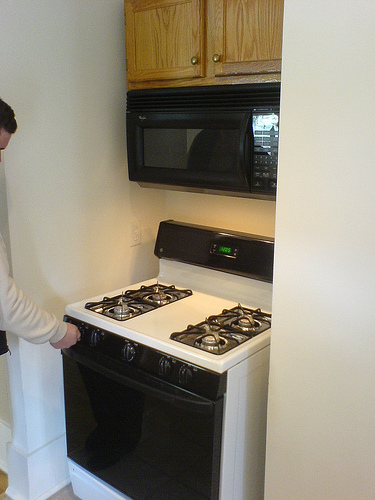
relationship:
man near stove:
[0, 99, 70, 499] [50, 223, 285, 499]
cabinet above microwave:
[125, 0, 284, 84] [116, 86, 282, 196]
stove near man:
[50, 223, 285, 499] [0, 99, 70, 499]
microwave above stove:
[116, 86, 282, 196] [50, 223, 285, 499]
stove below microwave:
[50, 223, 285, 499] [116, 86, 282, 196]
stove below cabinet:
[50, 223, 285, 499] [125, 0, 284, 84]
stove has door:
[61, 219, 275, 499] [61, 344, 223, 498]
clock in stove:
[216, 246, 229, 253] [50, 223, 285, 499]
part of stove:
[154, 218, 278, 284] [50, 223, 285, 499]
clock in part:
[216, 246, 229, 253] [154, 218, 278, 284]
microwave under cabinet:
[125, 91, 283, 196] [126, 2, 284, 84]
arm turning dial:
[0, 241, 70, 345] [72, 324, 84, 344]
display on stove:
[214, 242, 233, 256] [50, 223, 285, 499]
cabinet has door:
[126, 2, 284, 84] [126, 2, 206, 79]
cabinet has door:
[126, 2, 284, 84] [213, 3, 281, 75]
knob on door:
[190, 56, 197, 66] [122, 1, 207, 83]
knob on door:
[212, 54, 224, 64] [213, 3, 281, 75]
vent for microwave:
[125, 85, 282, 109] [116, 86, 282, 196]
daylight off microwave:
[250, 114, 279, 157] [116, 86, 282, 196]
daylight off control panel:
[250, 114, 279, 157] [252, 113, 277, 197]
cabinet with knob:
[126, 2, 284, 84] [190, 57, 202, 66]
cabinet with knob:
[126, 2, 284, 84] [210, 55, 222, 63]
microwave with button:
[116, 86, 282, 196] [252, 128, 262, 136]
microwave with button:
[116, 86, 282, 196] [261, 130, 269, 135]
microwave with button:
[116, 86, 282, 196] [268, 129, 277, 137]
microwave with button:
[116, 86, 282, 196] [252, 145, 265, 153]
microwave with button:
[116, 86, 282, 196] [262, 148, 270, 153]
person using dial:
[0, 100, 80, 490] [72, 324, 84, 344]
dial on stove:
[72, 324, 84, 344] [61, 219, 275, 499]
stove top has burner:
[67, 274, 272, 358] [88, 293, 158, 328]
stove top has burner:
[67, 274, 272, 358] [126, 279, 188, 306]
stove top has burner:
[67, 274, 272, 358] [169, 322, 251, 362]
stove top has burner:
[67, 274, 272, 358] [203, 302, 269, 340]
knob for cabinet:
[191, 56, 198, 66] [125, 0, 284, 84]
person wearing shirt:
[0, 100, 80, 490] [0, 255, 69, 344]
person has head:
[0, 100, 83, 349] [0, 97, 19, 163]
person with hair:
[0, 100, 83, 349] [0, 96, 18, 132]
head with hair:
[0, 97, 19, 163] [0, 96, 18, 132]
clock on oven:
[218, 246, 231, 254] [65, 215, 274, 498]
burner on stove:
[127, 281, 193, 307] [61, 219, 275, 499]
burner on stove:
[85, 293, 162, 322] [61, 219, 275, 499]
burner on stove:
[208, 302, 272, 338] [61, 219, 275, 499]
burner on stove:
[169, 321, 252, 356] [61, 219, 275, 499]